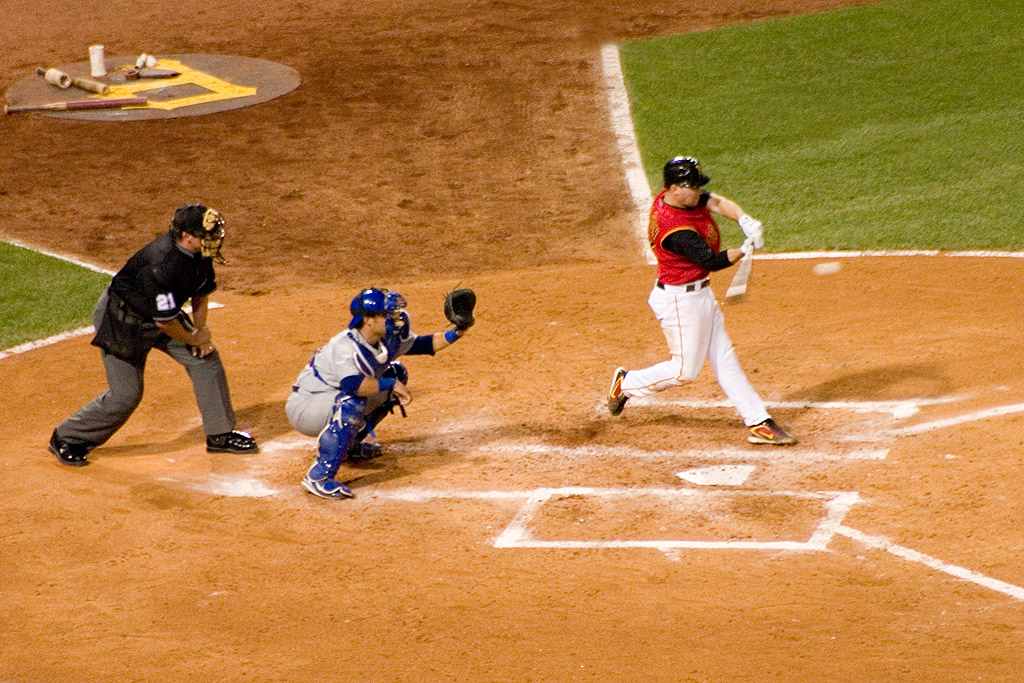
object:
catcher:
[285, 286, 477, 502]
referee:
[49, 207, 259, 467]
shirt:
[107, 235, 217, 321]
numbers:
[156, 293, 176, 311]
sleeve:
[143, 261, 186, 321]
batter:
[608, 156, 797, 446]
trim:
[659, 226, 702, 249]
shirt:
[647, 190, 734, 286]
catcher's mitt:
[443, 289, 476, 332]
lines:
[607, 35, 654, 268]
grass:
[764, 35, 978, 253]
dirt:
[402, 35, 612, 274]